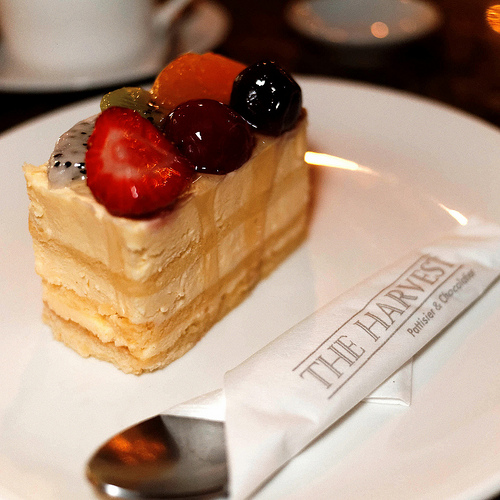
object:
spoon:
[85, 244, 482, 499]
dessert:
[13, 373, 499, 492]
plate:
[8, 82, 496, 490]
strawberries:
[46, 115, 194, 212]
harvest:
[292, 245, 454, 405]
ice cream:
[63, 221, 251, 363]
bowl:
[117, 419, 224, 487]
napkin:
[236, 287, 446, 479]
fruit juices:
[206, 184, 220, 325]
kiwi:
[97, 80, 170, 117]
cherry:
[156, 96, 264, 172]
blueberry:
[221, 56, 325, 137]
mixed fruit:
[43, 49, 308, 218]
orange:
[153, 44, 263, 109]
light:
[308, 147, 375, 179]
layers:
[45, 314, 149, 367]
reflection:
[115, 434, 173, 463]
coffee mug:
[4, 1, 194, 83]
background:
[5, 5, 500, 103]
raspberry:
[48, 114, 103, 186]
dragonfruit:
[147, 42, 253, 111]